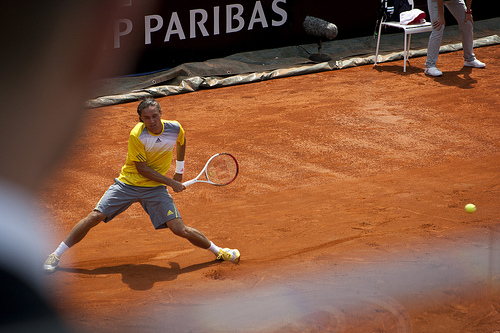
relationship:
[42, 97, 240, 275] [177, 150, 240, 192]
man holding racket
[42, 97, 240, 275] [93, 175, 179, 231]
man wearing shorts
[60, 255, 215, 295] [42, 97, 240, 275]
shadow of man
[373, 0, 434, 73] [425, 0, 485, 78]
bench by man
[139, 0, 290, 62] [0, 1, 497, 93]
paribas painted on wall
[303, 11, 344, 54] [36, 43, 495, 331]
microphone on edge of court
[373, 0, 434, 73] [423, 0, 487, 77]
bench for official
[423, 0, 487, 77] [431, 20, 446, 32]
official with hand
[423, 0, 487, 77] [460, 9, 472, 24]
official with hand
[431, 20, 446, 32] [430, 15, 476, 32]
hand on knees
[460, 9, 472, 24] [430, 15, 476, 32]
hand on knees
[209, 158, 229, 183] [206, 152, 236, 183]
w on webbing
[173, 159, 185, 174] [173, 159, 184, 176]
sweatband on wrist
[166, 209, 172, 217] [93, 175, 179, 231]
logo on shorts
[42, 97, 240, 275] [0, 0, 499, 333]
man on court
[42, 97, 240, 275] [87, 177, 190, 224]
man wearing gray pants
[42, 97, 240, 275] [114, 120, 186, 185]
man wearing shirt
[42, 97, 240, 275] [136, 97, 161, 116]
man with hair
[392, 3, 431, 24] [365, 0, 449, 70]
towel on bench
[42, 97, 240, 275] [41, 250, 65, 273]
man wearing sneakers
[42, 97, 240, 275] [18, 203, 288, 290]
man wearing sneakers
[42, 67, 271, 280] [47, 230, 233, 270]
man wearing socks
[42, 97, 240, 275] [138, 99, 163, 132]
man has head